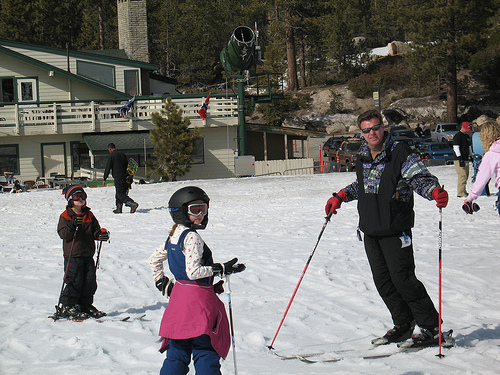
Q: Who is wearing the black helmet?
A: The girl.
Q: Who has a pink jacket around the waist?
A: The girl.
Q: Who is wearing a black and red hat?
A: The boy.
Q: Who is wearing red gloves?
A: The man.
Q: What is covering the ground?
A: Snow.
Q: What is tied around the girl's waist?
A: Pink jacket.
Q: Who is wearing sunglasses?
A: The man.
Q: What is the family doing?
A: Skiing.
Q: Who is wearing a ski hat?
A: The boy.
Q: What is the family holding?
A: Ski poles.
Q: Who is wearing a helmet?
A: The girl.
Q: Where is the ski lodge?
A: Behind the skiers.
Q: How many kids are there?
A: 2.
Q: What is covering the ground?
A: Snow.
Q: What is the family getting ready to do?
A: Ski.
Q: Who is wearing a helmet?
A: The girl.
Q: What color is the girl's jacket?
A: Pink.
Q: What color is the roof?
A: Green.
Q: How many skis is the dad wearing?
A: 2.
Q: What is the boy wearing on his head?
A: A hat.